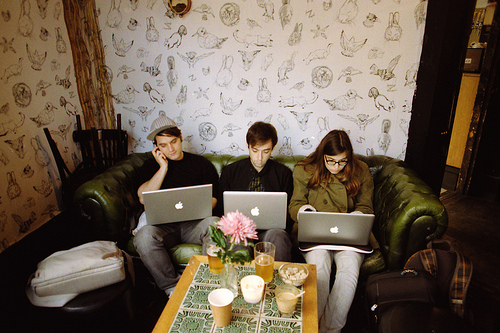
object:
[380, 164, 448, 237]
couch arm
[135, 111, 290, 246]
two men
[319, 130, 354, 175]
head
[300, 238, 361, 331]
pants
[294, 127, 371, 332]
girl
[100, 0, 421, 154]
wall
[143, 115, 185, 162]
head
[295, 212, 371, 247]
lap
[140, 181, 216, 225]
lap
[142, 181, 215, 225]
macbook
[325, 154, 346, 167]
glasses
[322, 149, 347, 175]
face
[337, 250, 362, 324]
leg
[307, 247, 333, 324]
leg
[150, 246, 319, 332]
table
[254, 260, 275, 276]
liquid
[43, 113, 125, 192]
chair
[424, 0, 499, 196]
doorway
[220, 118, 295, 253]
man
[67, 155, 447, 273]
couch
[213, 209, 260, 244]
flower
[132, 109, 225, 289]
man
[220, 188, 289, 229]
laptop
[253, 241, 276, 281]
glass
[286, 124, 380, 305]
person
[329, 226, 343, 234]
apple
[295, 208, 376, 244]
computer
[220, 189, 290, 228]
computer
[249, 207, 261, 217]
apple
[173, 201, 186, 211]
apple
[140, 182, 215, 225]
computer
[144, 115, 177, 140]
cap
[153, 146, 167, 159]
phone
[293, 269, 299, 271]
chips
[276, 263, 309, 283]
bowl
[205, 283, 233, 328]
cup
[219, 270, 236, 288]
vase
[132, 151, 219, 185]
shirt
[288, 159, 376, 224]
jacket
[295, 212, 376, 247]
macbook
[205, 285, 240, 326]
cup